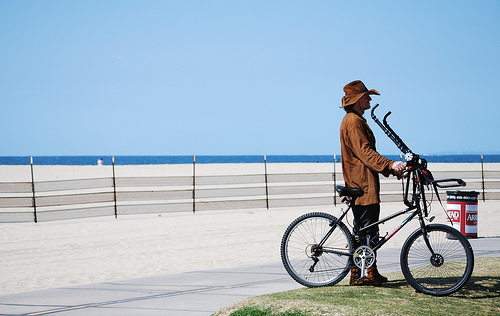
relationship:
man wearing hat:
[333, 74, 398, 284] [332, 76, 383, 108]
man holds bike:
[333, 74, 398, 284] [278, 162, 478, 302]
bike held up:
[278, 162, 478, 302] [278, 154, 474, 300]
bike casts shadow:
[278, 162, 478, 302] [381, 270, 492, 290]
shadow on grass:
[381, 270, 492, 290] [282, 276, 496, 311]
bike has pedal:
[278, 162, 478, 302] [303, 245, 326, 274]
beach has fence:
[45, 147, 224, 221] [29, 157, 291, 211]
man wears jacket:
[333, 74, 398, 284] [333, 111, 393, 208]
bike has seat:
[278, 162, 478, 302] [336, 182, 366, 201]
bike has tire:
[278, 162, 478, 302] [401, 223, 475, 299]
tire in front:
[401, 223, 475, 299] [375, 199, 479, 302]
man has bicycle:
[333, 74, 398, 284] [278, 162, 478, 302]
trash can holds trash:
[443, 190, 486, 248] [447, 186, 481, 200]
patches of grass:
[207, 277, 375, 313] [282, 276, 496, 311]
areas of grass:
[216, 258, 496, 314] [282, 276, 496, 311]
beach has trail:
[45, 147, 224, 221] [2, 243, 496, 311]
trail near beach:
[2, 243, 496, 311] [45, 147, 224, 221]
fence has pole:
[29, 157, 291, 211] [186, 154, 207, 214]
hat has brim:
[332, 76, 383, 108] [367, 82, 382, 102]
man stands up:
[333, 74, 398, 284] [278, 154, 474, 300]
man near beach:
[333, 74, 398, 284] [45, 147, 224, 221]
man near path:
[333, 74, 398, 284] [193, 227, 498, 279]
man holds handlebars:
[333, 74, 398, 284] [389, 155, 438, 207]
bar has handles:
[401, 185, 424, 207] [396, 161, 441, 186]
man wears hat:
[333, 74, 398, 284] [332, 76, 383, 108]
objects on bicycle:
[369, 100, 443, 194] [278, 162, 478, 302]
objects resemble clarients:
[369, 100, 443, 194] [372, 102, 419, 158]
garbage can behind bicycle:
[443, 190, 486, 248] [278, 162, 478, 302]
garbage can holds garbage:
[443, 190, 486, 248] [447, 186, 481, 200]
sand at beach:
[91, 230, 169, 262] [45, 147, 224, 221]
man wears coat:
[333, 74, 398, 284] [333, 111, 393, 208]